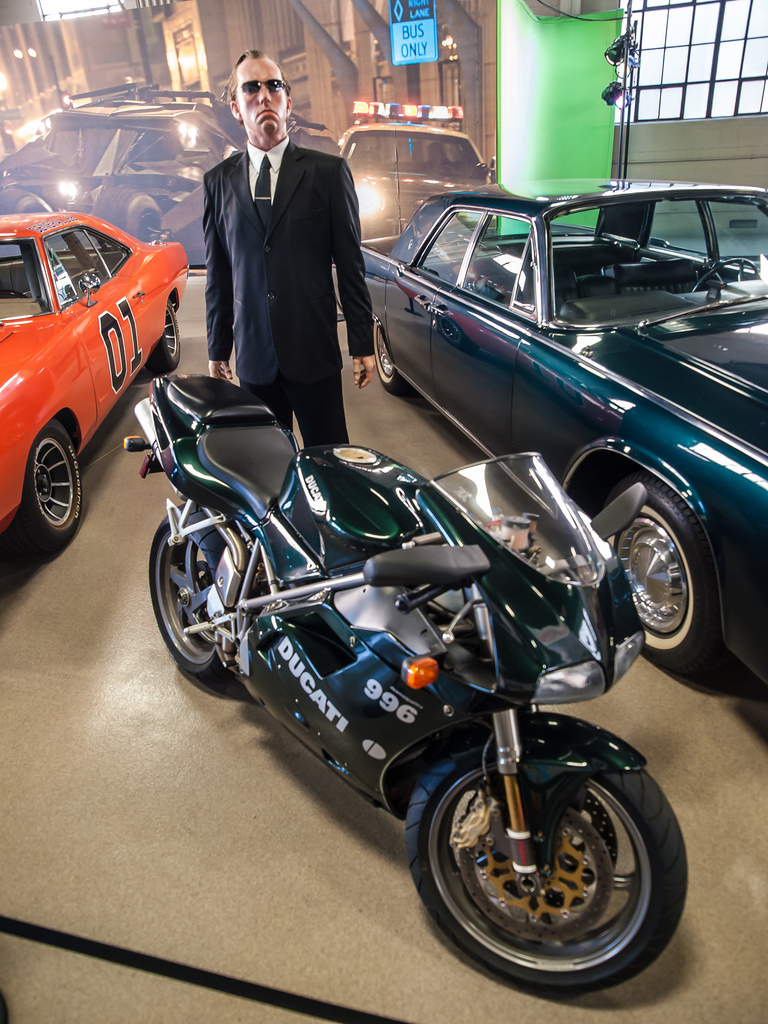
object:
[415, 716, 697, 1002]
tire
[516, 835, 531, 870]
stripe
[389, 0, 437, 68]
signage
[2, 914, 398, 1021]
stripe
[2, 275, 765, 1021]
floor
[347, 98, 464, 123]
police lights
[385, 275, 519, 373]
reflection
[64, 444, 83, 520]
letterings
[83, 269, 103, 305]
side mirror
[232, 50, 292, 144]
face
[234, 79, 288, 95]
sunglasses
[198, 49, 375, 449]
man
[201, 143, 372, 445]
suit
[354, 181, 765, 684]
car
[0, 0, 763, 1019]
garage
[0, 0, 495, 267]
mural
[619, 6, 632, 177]
pole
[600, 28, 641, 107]
lights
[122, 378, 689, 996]
bike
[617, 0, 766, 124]
windows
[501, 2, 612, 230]
green screen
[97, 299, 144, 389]
number